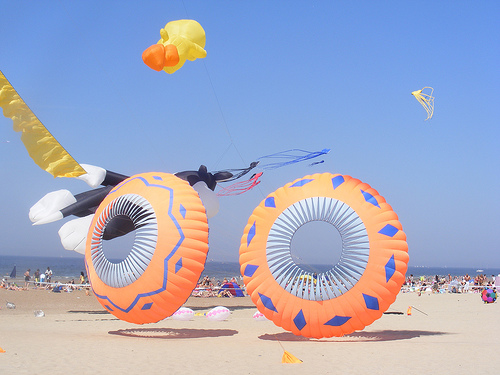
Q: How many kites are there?
A: Seven.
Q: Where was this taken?
A: On the beach.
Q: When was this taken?
A: During the day.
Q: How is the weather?
A: It is sunny.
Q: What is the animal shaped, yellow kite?
A: Tweety Bird.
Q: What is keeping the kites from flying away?
A: They are tethered to the ground.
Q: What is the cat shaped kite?
A: Sylvester the cat.